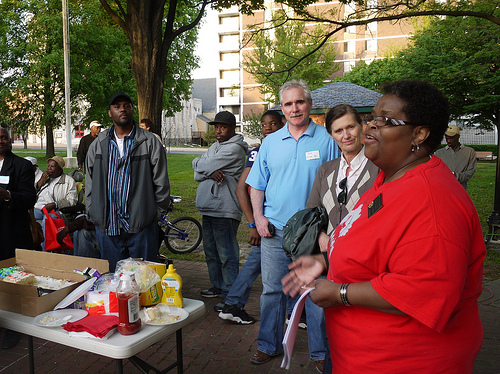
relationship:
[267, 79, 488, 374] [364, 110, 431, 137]
woman wears glasses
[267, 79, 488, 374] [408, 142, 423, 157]
woman wears earring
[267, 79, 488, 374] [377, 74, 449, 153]
woman has hair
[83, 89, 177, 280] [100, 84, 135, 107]
man wears cap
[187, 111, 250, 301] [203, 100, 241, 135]
man wears cap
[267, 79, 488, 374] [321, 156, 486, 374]
woman wears shirt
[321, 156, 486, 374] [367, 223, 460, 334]
shirt has sleeve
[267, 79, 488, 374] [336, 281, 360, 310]
woman wears bracelet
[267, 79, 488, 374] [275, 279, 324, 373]
woman holds paper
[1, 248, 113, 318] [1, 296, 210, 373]
cake on table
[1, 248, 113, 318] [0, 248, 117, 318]
cake in box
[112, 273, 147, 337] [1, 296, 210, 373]
ketchup on table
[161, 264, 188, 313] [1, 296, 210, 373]
mustard on table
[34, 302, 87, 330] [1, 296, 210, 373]
plate on table